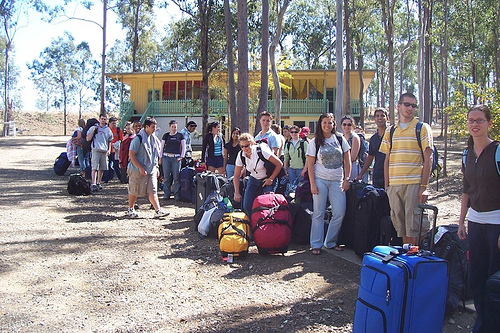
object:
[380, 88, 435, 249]
person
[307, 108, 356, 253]
camper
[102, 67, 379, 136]
cabin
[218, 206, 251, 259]
bag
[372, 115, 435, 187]
shirt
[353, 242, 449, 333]
luggage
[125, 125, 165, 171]
sweatshirt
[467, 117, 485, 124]
glasses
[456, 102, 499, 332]
girl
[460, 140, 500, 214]
vest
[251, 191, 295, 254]
duffel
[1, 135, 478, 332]
road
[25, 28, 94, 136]
tree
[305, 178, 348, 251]
jeans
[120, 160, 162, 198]
shorts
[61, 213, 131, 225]
shadow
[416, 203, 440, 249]
handle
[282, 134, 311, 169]
top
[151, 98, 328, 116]
railing